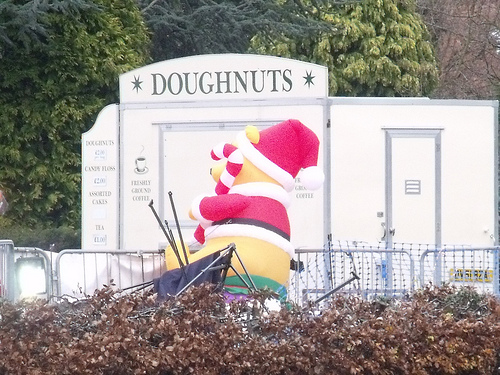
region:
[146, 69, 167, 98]
The letter is black.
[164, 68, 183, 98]
The letter is black.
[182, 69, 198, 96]
The letter is black.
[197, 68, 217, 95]
The letter is black.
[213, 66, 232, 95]
The letter is black.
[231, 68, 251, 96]
The letter is black.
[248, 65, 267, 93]
The letter is black.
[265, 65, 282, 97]
The letter is black.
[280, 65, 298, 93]
The letter is black.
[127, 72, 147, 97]
The star is black.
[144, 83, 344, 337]
an inflatable balloon by the fence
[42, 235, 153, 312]
the fence is gray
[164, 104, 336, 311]
large winnie the pooh ballon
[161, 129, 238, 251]
bear holding a large candy cane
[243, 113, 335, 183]
hat on a teddy bear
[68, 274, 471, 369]
leaves on the ground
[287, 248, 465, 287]
gate in front of a bear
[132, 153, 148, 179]
coffee mug picture on the wall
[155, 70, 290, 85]
doughnuts on a building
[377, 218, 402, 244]
handle on a door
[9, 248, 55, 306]
mirror on the fence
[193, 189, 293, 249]
bear wearing a red jacket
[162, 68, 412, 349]
a blow up statue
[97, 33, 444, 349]
a blow up bear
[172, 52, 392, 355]
a winnie the pooh bear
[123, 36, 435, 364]
winnie the pooh blow up bear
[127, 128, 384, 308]
a bear wearing a hat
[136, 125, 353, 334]
a bear wearing a red hat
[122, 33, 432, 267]
a sign above a trailer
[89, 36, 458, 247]
a sign that says doughnuts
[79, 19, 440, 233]
a white trailer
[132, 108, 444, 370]
a bear holding a candy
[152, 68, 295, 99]
word "doughnuts" on white building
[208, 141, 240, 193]
top of candy cane held by inflatable winnie the pooh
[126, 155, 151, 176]
drawing of coffee cup on white building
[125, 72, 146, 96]
star next to the "D" in doughnuts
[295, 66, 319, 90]
star next to the "S" in doughnuts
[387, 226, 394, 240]
silver door handle on white building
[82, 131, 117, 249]
writing alongside of white building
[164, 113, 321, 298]
Winnie the Pooh inflatable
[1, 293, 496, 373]
brown hedge along bottom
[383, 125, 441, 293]
tall, narrow door in white building